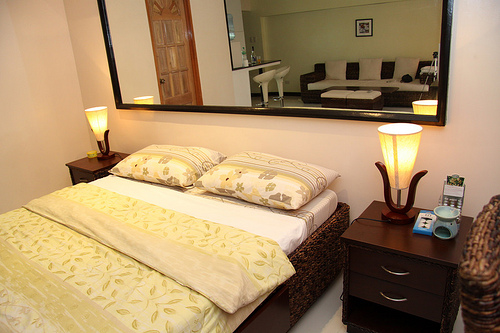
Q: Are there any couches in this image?
A: Yes, there is a couch.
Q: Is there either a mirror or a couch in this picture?
A: Yes, there is a couch.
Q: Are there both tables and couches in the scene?
A: Yes, there are both a couch and a table.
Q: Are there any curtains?
A: No, there are no curtains.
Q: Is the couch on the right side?
A: Yes, the couch is on the right of the image.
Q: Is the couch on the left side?
A: No, the couch is on the right of the image.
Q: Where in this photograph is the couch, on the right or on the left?
A: The couch is on the right of the image.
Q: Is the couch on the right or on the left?
A: The couch is on the right of the image.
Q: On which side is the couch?
A: The couch is on the right of the image.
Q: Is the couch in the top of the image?
A: Yes, the couch is in the top of the image.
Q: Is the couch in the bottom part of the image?
A: No, the couch is in the top of the image.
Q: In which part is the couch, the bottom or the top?
A: The couch is in the top of the image.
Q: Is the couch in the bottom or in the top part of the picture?
A: The couch is in the top of the image.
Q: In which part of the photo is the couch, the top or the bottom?
A: The couch is in the top of the image.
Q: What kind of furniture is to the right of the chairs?
A: The piece of furniture is a couch.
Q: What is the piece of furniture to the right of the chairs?
A: The piece of furniture is a couch.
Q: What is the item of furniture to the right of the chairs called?
A: The piece of furniture is a couch.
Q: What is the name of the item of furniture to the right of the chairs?
A: The piece of furniture is a couch.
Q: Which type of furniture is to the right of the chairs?
A: The piece of furniture is a couch.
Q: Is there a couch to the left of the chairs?
A: No, the couch is to the right of the chairs.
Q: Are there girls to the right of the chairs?
A: No, there is a couch to the right of the chairs.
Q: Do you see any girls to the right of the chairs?
A: No, there is a couch to the right of the chairs.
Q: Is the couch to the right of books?
A: No, the couch is to the right of the chairs.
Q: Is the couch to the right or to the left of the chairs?
A: The couch is to the right of the chairs.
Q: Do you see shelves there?
A: No, there are no shelves.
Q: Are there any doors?
A: Yes, there is a door.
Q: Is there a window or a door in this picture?
A: Yes, there is a door.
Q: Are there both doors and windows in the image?
A: No, there is a door but no windows.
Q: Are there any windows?
A: No, there are no windows.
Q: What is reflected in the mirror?
A: The door is reflected in the mirror.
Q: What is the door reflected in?
A: The door is reflected in the mirror.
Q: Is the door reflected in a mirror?
A: Yes, the door is reflected in a mirror.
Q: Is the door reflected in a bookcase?
A: No, the door is reflected in a mirror.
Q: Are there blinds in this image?
A: No, there are no blinds.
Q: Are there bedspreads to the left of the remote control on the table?
A: Yes, there is a bedspread to the left of the remote.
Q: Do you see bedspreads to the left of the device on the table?
A: Yes, there is a bedspread to the left of the remote.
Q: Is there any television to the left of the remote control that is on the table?
A: No, there is a bedspread to the left of the remote control.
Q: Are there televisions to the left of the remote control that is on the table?
A: No, there is a bedspread to the left of the remote control.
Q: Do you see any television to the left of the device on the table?
A: No, there is a bedspread to the left of the remote control.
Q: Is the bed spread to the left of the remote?
A: Yes, the bed spread is to the left of the remote.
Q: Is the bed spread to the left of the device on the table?
A: Yes, the bed spread is to the left of the remote.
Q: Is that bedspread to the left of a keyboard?
A: No, the bedspread is to the left of the remote.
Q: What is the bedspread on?
A: The bedspread is on the bed.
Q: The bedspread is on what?
A: The bedspread is on the bed.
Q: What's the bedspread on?
A: The bedspread is on the bed.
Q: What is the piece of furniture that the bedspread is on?
A: The piece of furniture is a bed.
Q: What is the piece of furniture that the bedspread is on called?
A: The piece of furniture is a bed.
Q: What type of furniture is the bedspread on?
A: The bedspread is on the bed.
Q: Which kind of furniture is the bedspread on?
A: The bedspread is on the bed.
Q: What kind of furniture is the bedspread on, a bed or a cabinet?
A: The bedspread is on a bed.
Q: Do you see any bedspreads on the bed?
A: Yes, there is a bedspread on the bed.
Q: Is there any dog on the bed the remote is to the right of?
A: No, there is a bedspread on the bed.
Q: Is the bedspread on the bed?
A: Yes, the bedspread is on the bed.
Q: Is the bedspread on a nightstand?
A: No, the bedspread is on the bed.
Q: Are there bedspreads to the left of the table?
A: Yes, there is a bedspread to the left of the table.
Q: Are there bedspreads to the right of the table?
A: No, the bedspread is to the left of the table.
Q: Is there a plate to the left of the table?
A: No, there is a bedspread to the left of the table.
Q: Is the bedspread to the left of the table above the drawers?
A: Yes, the bedspread is to the left of the table.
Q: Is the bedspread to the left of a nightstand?
A: No, the bedspread is to the left of the table.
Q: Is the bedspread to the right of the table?
A: No, the bedspread is to the left of the table.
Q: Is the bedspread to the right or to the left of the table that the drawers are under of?
A: The bedspread is to the left of the table.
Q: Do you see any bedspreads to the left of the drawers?
A: Yes, there is a bedspread to the left of the drawers.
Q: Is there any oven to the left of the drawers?
A: No, there is a bedspread to the left of the drawers.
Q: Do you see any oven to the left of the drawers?
A: No, there is a bedspread to the left of the drawers.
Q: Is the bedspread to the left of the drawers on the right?
A: Yes, the bedspread is to the left of the drawers.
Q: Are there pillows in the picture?
A: Yes, there are pillows.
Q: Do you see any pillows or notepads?
A: Yes, there are pillows.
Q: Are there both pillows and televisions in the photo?
A: No, there are pillows but no televisions.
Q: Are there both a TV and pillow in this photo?
A: No, there are pillows but no televisions.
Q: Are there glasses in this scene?
A: No, there are no glasses.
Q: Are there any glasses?
A: No, there are no glasses.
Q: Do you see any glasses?
A: No, there are no glasses.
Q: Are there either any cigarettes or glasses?
A: No, there are no glasses or cigarettes.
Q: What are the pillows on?
A: The pillows are on the bed.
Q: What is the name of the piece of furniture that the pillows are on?
A: The piece of furniture is a bed.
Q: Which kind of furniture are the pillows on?
A: The pillows are on the bed.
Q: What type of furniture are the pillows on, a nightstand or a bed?
A: The pillows are on a bed.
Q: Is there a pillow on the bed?
A: Yes, there are pillows on the bed.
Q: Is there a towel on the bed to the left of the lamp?
A: No, there are pillows on the bed.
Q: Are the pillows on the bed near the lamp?
A: Yes, the pillows are on the bed.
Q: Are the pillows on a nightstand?
A: No, the pillows are on the bed.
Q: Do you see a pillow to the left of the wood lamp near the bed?
A: Yes, there are pillows to the left of the lamp.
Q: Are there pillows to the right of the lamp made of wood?
A: No, the pillows are to the left of the lamp.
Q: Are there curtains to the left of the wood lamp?
A: No, there are pillows to the left of the lamp.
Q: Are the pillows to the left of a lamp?
A: Yes, the pillows are to the left of a lamp.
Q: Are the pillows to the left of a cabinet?
A: No, the pillows are to the left of a lamp.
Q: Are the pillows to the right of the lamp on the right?
A: No, the pillows are to the left of the lamp.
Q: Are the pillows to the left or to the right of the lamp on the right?
A: The pillows are to the left of the lamp.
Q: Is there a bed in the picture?
A: Yes, there is a bed.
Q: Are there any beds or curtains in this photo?
A: Yes, there is a bed.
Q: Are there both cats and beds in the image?
A: No, there is a bed but no cats.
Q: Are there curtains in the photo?
A: No, there are no curtains.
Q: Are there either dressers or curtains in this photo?
A: No, there are no curtains or dressers.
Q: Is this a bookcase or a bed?
A: This is a bed.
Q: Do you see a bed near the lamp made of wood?
A: Yes, there is a bed near the lamp.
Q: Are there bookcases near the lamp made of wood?
A: No, there is a bed near the lamp.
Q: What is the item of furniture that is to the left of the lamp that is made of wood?
A: The piece of furniture is a bed.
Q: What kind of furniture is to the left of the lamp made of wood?
A: The piece of furniture is a bed.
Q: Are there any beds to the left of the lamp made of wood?
A: Yes, there is a bed to the left of the lamp.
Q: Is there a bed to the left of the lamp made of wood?
A: Yes, there is a bed to the left of the lamp.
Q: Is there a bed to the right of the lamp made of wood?
A: No, the bed is to the left of the lamp.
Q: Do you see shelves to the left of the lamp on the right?
A: No, there is a bed to the left of the lamp.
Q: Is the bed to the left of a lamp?
A: Yes, the bed is to the left of a lamp.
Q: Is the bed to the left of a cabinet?
A: No, the bed is to the left of a lamp.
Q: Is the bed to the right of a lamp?
A: No, the bed is to the left of a lamp.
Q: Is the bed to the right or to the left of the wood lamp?
A: The bed is to the left of the lamp.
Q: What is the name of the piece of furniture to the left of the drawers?
A: The piece of furniture is a bed.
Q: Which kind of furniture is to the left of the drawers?
A: The piece of furniture is a bed.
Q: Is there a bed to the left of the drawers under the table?
A: Yes, there is a bed to the left of the drawers.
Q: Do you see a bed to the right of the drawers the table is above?
A: No, the bed is to the left of the drawers.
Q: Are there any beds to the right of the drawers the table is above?
A: No, the bed is to the left of the drawers.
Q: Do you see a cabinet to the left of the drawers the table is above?
A: No, there is a bed to the left of the drawers.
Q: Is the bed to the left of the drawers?
A: Yes, the bed is to the left of the drawers.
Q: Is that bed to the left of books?
A: No, the bed is to the left of the drawers.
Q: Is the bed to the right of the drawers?
A: No, the bed is to the left of the drawers.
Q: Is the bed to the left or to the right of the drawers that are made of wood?
A: The bed is to the left of the drawers.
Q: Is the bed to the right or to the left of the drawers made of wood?
A: The bed is to the left of the drawers.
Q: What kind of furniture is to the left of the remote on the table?
A: The piece of furniture is a bed.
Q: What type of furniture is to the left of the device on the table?
A: The piece of furniture is a bed.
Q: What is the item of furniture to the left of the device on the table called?
A: The piece of furniture is a bed.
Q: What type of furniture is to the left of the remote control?
A: The piece of furniture is a bed.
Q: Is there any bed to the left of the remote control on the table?
A: Yes, there is a bed to the left of the remote control.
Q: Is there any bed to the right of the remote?
A: No, the bed is to the left of the remote.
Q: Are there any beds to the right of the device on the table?
A: No, the bed is to the left of the remote.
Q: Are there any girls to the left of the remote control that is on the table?
A: No, there is a bed to the left of the remote control.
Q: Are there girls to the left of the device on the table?
A: No, there is a bed to the left of the remote control.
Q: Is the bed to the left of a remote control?
A: Yes, the bed is to the left of a remote control.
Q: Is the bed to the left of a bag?
A: No, the bed is to the left of a remote control.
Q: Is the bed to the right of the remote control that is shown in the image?
A: No, the bed is to the left of the remote control.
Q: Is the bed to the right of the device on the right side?
A: No, the bed is to the left of the remote control.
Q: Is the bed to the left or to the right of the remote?
A: The bed is to the left of the remote.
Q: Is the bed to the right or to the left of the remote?
A: The bed is to the left of the remote.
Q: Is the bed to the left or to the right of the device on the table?
A: The bed is to the left of the remote.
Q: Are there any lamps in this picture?
A: Yes, there is a lamp.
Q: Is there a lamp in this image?
A: Yes, there is a lamp.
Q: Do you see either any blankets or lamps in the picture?
A: Yes, there is a lamp.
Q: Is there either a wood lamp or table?
A: Yes, there is a wood lamp.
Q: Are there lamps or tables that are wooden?
A: Yes, the lamp is wooden.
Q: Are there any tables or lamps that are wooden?
A: Yes, the lamp is wooden.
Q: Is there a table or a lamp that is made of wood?
A: Yes, the lamp is made of wood.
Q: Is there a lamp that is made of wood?
A: Yes, there is a lamp that is made of wood.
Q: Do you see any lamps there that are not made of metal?
A: Yes, there is a lamp that is made of wood.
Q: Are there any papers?
A: No, there are no papers.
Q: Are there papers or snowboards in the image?
A: No, there are no papers or snowboards.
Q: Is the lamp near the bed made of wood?
A: Yes, the lamp is made of wood.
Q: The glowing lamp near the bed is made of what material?
A: The lamp is made of wood.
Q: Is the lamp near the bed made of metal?
A: No, the lamp is made of wood.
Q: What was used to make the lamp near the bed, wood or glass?
A: The lamp is made of wood.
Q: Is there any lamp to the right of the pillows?
A: Yes, there is a lamp to the right of the pillows.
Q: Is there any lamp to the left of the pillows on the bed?
A: No, the lamp is to the right of the pillows.